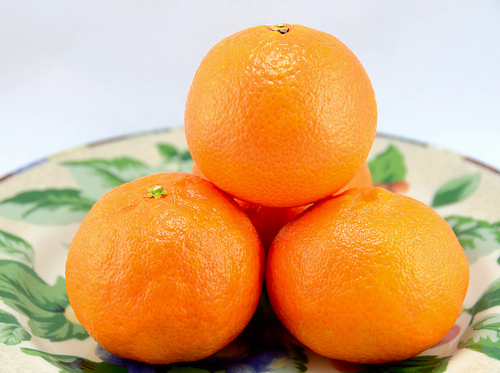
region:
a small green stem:
[141, 176, 173, 210]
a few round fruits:
[44, 11, 485, 371]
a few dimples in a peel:
[244, 32, 314, 92]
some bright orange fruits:
[58, 6, 488, 368]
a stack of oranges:
[44, 13, 486, 361]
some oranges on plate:
[9, 19, 452, 357]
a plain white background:
[18, 18, 145, 120]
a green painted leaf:
[3, 179, 84, 234]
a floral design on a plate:
[14, 97, 458, 364]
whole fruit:
[58, 165, 269, 371]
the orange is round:
[180, 26, 390, 205]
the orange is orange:
[150, 4, 401, 232]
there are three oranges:
[59, 12, 478, 367]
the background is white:
[11, 10, 131, 115]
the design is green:
[0, 227, 72, 341]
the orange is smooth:
[193, 37, 386, 209]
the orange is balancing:
[60, 20, 476, 358]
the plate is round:
[13, 93, 496, 364]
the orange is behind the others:
[188, 139, 380, 257]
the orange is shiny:
[172, 15, 382, 220]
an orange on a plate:
[270, 186, 465, 361]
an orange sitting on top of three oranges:
[180, 21, 376, 207]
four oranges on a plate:
[66, 20, 469, 360]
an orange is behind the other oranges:
[186, 160, 371, 260]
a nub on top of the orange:
[265, 16, 290, 32]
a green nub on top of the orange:
[141, 181, 169, 201]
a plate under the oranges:
[2, 120, 497, 368]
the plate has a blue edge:
[2, 120, 497, 365]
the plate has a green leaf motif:
[1, 120, 492, 370]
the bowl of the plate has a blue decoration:
[91, 315, 313, 371]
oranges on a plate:
[55, 12, 463, 368]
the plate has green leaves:
[4, 235, 68, 370]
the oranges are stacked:
[78, 36, 456, 367]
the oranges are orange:
[63, 45, 440, 363]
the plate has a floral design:
[47, 320, 312, 371]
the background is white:
[4, 37, 215, 118]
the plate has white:
[15, 219, 68, 277]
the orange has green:
[145, 182, 172, 199]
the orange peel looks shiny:
[220, 56, 322, 95]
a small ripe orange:
[182, 21, 378, 209]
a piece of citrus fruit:
[182, 8, 382, 189]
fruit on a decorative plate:
[0, 116, 499, 371]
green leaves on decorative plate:
[428, 165, 486, 210]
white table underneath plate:
[43, 92, 133, 128]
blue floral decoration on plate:
[218, 339, 290, 369]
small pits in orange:
[250, 76, 322, 146]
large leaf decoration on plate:
[55, 154, 162, 201]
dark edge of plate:
[64, 113, 165, 154]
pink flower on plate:
[428, 317, 460, 349]